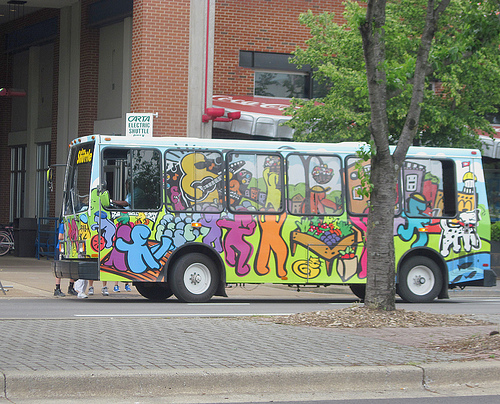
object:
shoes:
[53, 284, 70, 296]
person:
[44, 261, 85, 301]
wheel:
[392, 244, 449, 305]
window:
[247, 67, 334, 104]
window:
[235, 45, 320, 69]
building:
[0, 1, 500, 291]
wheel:
[169, 248, 218, 303]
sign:
[123, 110, 153, 137]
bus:
[52, 134, 498, 303]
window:
[99, 147, 166, 211]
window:
[163, 147, 224, 210]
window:
[62, 139, 95, 211]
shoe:
[91, 281, 111, 298]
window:
[287, 147, 344, 218]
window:
[223, 149, 282, 211]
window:
[400, 155, 456, 217]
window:
[345, 153, 401, 218]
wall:
[348, 183, 378, 228]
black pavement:
[9, 298, 196, 311]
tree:
[288, 0, 500, 316]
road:
[0, 297, 499, 402]